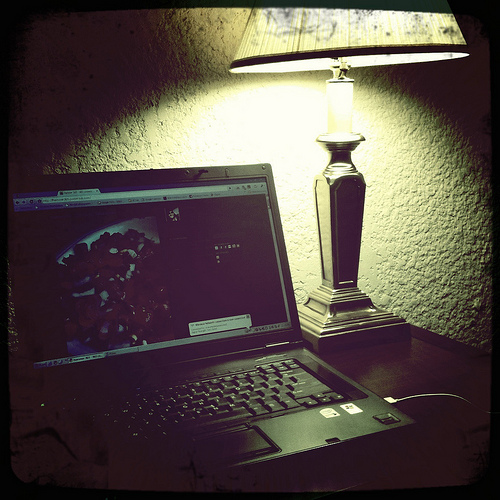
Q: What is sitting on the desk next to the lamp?
A: A laptop.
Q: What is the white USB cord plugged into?
A: The laptop.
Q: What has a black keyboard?
A: The laptop.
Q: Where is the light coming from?
A: The lamp.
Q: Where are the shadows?
A: On the wall.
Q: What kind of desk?
A: Wood.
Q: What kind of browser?
A: Chrome.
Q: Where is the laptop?
A: Desk.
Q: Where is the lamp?
A: On the right.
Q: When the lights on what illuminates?
A: Light.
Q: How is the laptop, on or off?
A: On.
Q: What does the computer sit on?
A: Desk.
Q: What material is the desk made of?
A: Wood.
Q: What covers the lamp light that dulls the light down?
A: Shade.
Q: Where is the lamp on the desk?
A: Corner.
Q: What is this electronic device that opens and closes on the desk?
A: Laptop.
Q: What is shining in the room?
A: Light.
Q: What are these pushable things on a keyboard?
A: Keys.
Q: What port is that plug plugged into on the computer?
A: USB.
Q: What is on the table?
A: Laptop.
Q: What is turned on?
A: The light.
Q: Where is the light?
A: Next to laptop.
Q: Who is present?
A: No one.